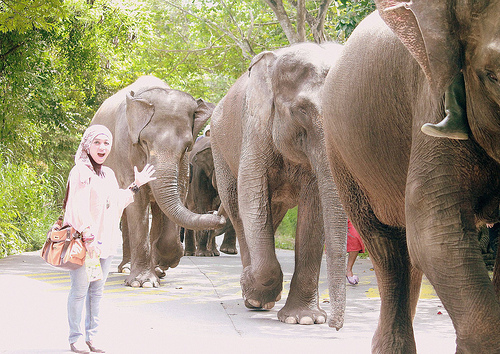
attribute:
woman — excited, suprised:
[41, 119, 145, 353]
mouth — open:
[95, 149, 110, 161]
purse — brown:
[39, 218, 97, 271]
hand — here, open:
[133, 167, 165, 191]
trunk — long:
[299, 156, 367, 340]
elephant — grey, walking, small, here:
[204, 14, 347, 340]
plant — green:
[7, 42, 59, 257]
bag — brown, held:
[27, 218, 100, 279]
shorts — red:
[338, 213, 368, 263]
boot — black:
[85, 324, 97, 350]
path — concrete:
[127, 282, 224, 340]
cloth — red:
[343, 213, 368, 265]